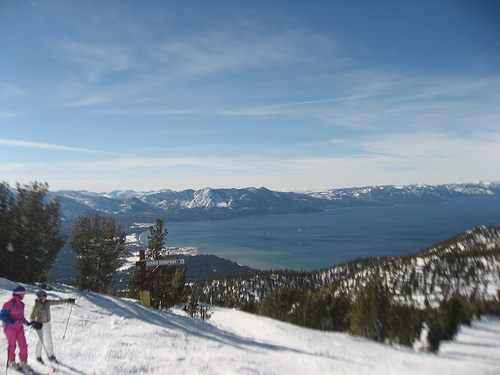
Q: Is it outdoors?
A: Yes, it is outdoors.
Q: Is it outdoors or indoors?
A: It is outdoors.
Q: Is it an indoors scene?
A: No, it is outdoors.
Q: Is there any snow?
A: Yes, there is snow.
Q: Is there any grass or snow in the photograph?
A: Yes, there is snow.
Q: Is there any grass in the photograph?
A: No, there is no grass.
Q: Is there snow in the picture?
A: Yes, there is snow.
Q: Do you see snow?
A: Yes, there is snow.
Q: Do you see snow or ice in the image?
A: Yes, there is snow.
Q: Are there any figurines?
A: No, there are no figurines.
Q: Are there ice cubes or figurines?
A: No, there are no figurines or ice cubes.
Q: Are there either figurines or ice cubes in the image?
A: No, there are no figurines or ice cubes.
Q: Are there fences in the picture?
A: No, there are no fences.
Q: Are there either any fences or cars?
A: No, there are no fences or cars.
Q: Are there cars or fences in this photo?
A: No, there are no fences or cars.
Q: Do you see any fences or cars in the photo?
A: No, there are no fences or cars.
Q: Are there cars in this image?
A: No, there are no cars.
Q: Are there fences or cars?
A: No, there are no cars or fences.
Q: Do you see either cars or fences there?
A: No, there are no cars or fences.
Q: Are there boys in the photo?
A: No, there are no boys.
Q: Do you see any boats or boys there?
A: No, there are no boys or boats.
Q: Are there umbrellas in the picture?
A: No, there are no umbrellas.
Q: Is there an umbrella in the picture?
A: No, there are no umbrellas.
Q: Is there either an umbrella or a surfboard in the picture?
A: No, there are no umbrellas or surfboards.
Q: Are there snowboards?
A: No, there are no snowboards.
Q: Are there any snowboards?
A: No, there are no snowboards.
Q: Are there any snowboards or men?
A: No, there are no snowboards or men.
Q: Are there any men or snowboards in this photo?
A: No, there are no snowboards or men.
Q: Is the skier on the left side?
A: Yes, the skier is on the left of the image.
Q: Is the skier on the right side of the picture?
A: No, the skier is on the left of the image.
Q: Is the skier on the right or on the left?
A: The skier is on the left of the image.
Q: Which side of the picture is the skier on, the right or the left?
A: The skier is on the left of the image.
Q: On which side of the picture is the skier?
A: The skier is on the left of the image.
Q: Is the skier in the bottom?
A: Yes, the skier is in the bottom of the image.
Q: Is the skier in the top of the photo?
A: No, the skier is in the bottom of the image.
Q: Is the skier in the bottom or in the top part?
A: The skier is in the bottom of the image.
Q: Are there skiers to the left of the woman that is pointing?
A: Yes, there is a skier to the left of the woman.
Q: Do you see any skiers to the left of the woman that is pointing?
A: Yes, there is a skier to the left of the woman.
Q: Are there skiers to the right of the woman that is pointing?
A: No, the skier is to the left of the woman.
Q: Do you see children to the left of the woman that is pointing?
A: No, there is a skier to the left of the woman.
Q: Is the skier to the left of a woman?
A: Yes, the skier is to the left of a woman.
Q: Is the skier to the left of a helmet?
A: No, the skier is to the left of a woman.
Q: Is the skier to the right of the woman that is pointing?
A: No, the skier is to the left of the woman.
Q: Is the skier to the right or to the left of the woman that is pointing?
A: The skier is to the left of the woman.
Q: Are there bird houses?
A: No, there are no bird houses.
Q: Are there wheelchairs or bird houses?
A: No, there are no bird houses or wheelchairs.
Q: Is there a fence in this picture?
A: No, there are no fences.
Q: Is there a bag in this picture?
A: No, there are no bags.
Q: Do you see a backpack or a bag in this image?
A: No, there are no bags or backpacks.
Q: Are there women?
A: Yes, there are women.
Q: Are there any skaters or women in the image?
A: Yes, there are women.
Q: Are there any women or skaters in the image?
A: Yes, there are women.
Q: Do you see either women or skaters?
A: Yes, there are women.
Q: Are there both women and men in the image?
A: No, there are women but no men.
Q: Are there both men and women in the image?
A: No, there are women but no men.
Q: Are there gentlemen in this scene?
A: No, there are no gentlemen.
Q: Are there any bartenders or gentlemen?
A: No, there are no gentlemen or bartenders.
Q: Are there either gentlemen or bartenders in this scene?
A: No, there are no gentlemen or bartenders.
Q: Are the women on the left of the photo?
A: Yes, the women are on the left of the image.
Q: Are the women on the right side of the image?
A: No, the women are on the left of the image.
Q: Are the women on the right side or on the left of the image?
A: The women are on the left of the image.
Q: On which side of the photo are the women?
A: The women are on the left of the image.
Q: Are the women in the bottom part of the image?
A: Yes, the women are in the bottom of the image.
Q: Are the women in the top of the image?
A: No, the women are in the bottom of the image.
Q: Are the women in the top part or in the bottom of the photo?
A: The women are in the bottom of the image.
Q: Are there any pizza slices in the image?
A: No, there are no pizza slices.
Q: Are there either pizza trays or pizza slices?
A: No, there are no pizza slices or pizza trays.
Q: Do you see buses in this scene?
A: No, there are no buses.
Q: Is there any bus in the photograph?
A: No, there are no buses.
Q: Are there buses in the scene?
A: No, there are no buses.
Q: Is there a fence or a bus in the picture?
A: No, there are no buses or fences.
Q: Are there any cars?
A: No, there are no cars.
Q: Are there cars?
A: No, there are no cars.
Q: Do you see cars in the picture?
A: No, there are no cars.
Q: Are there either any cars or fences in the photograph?
A: No, there are no cars or fences.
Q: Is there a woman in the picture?
A: Yes, there is a woman.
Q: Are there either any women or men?
A: Yes, there is a woman.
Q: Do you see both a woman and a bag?
A: No, there is a woman but no bags.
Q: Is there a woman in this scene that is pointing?
A: Yes, there is a woman that is pointing.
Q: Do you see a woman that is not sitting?
A: Yes, there is a woman that is pointing .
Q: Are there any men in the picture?
A: No, there are no men.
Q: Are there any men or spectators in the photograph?
A: No, there are no men or spectators.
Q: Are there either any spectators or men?
A: No, there are no men or spectators.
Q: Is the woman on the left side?
A: Yes, the woman is on the left of the image.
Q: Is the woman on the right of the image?
A: No, the woman is on the left of the image.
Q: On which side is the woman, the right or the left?
A: The woman is on the left of the image.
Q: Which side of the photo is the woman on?
A: The woman is on the left of the image.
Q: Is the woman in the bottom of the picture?
A: Yes, the woman is in the bottom of the image.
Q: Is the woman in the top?
A: No, the woman is in the bottom of the image.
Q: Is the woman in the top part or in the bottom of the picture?
A: The woman is in the bottom of the image.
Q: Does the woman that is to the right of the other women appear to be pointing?
A: Yes, the woman is pointing.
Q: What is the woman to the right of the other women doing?
A: The woman is pointing.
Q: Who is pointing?
A: The woman is pointing.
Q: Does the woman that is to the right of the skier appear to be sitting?
A: No, the woman is pointing.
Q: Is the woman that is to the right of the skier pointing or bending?
A: The woman is pointing.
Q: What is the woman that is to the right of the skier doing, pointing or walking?
A: The woman is pointing.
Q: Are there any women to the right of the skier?
A: Yes, there is a woman to the right of the skier.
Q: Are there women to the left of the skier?
A: No, the woman is to the right of the skier.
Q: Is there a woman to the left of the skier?
A: No, the woman is to the right of the skier.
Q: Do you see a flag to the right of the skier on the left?
A: No, there is a woman to the right of the skier.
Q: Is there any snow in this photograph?
A: Yes, there is snow.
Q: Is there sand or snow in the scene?
A: Yes, there is snow.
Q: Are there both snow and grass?
A: No, there is snow but no grass.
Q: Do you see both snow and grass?
A: No, there is snow but no grass.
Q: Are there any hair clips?
A: No, there are no hair clips.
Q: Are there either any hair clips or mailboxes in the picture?
A: No, there are no hair clips or mailboxes.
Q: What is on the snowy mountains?
A: The snow is on the mountains.